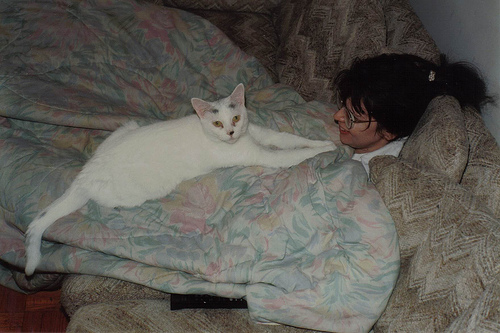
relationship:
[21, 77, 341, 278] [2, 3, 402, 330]
cat on comforter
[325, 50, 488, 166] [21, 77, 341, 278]
woman looking at cat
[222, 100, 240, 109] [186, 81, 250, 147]
spot on head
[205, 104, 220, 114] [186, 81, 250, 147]
spot on head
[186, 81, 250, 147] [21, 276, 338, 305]
head on cat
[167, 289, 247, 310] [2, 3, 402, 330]
remote control under comforter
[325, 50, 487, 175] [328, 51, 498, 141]
woman has hair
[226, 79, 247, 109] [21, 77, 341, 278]
ear on cat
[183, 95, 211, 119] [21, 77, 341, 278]
ear on cat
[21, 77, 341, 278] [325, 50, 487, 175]
cat in front of woman